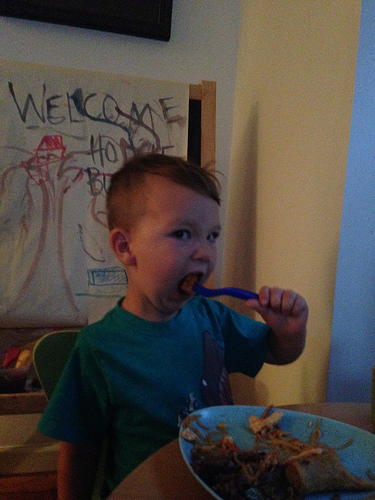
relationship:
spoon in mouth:
[191, 281, 260, 302] [136, 252, 227, 307]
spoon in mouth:
[191, 281, 260, 302] [132, 262, 220, 311]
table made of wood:
[122, 399, 362, 498] [95, 395, 373, 497]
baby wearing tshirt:
[32, 152, 309, 500] [35, 289, 274, 450]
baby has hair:
[26, 120, 319, 493] [157, 154, 226, 205]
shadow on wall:
[218, 107, 258, 404] [211, 0, 357, 407]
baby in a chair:
[32, 152, 309, 500] [30, 325, 221, 498]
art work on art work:
[5, 61, 99, 336] [0, 67, 190, 329]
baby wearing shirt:
[32, 152, 309, 500] [35, 293, 270, 485]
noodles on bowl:
[247, 414, 321, 465] [176, 402, 374, 500]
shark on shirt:
[197, 329, 232, 402] [35, 293, 270, 485]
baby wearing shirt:
[32, 152, 309, 500] [34, 293, 269, 500]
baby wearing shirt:
[32, 152, 309, 500] [34, 288, 275, 497]